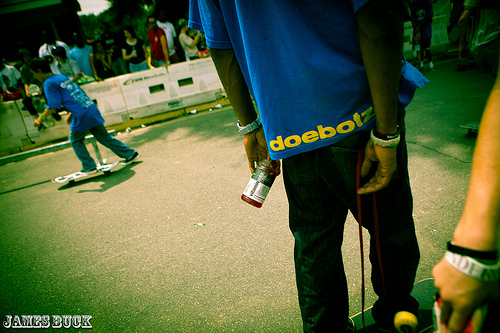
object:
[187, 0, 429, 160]
blue shirt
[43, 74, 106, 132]
blue shirt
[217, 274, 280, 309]
concrete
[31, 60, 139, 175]
boy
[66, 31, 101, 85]
man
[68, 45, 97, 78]
shirt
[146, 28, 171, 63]
shirt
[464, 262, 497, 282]
lettering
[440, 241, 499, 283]
wristband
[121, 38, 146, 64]
shirt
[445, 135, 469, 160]
ground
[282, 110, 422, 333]
jeans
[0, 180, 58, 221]
pavement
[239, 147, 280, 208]
bottle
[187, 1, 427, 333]
boy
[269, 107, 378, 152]
lettering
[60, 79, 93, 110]
lettering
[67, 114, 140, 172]
jeans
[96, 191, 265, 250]
squares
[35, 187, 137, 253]
cement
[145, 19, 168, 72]
man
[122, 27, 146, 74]
woman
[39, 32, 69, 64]
man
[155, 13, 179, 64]
man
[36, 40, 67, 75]
shirt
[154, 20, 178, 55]
shirt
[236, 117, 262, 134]
bracelet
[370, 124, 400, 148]
bracelet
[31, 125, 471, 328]
sunlight patch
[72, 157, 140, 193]
shadow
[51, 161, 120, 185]
skateboard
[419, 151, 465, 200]
pavement